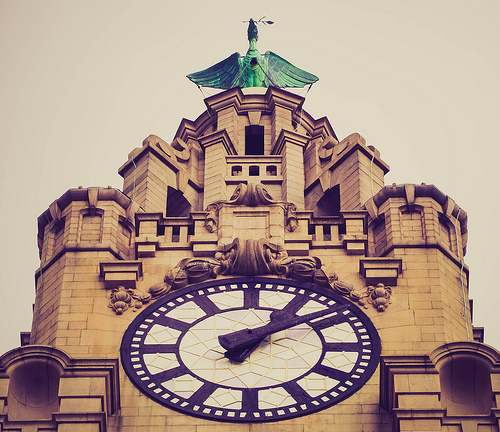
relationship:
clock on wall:
[197, 281, 362, 401] [51, 243, 466, 428]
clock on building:
[119, 278, 381, 424] [2, 8, 499, 430]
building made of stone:
[79, 175, 429, 427] [409, 257, 441, 297]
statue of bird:
[185, 16, 319, 90] [184, 12, 321, 91]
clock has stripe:
[119, 278, 381, 424] [241, 277, 262, 309]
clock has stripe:
[119, 278, 381, 424] [187, 295, 221, 319]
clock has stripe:
[119, 278, 381, 424] [149, 308, 186, 337]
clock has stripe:
[119, 278, 381, 424] [135, 337, 176, 357]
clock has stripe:
[119, 278, 381, 424] [238, 383, 261, 419]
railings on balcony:
[57, 169, 497, 251] [51, 192, 461, 268]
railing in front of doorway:
[226, 151, 283, 185] [240, 117, 269, 157]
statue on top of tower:
[183, 24, 265, 94] [178, 44, 422, 345]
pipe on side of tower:
[363, 145, 383, 203] [91, 83, 464, 353]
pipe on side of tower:
[127, 151, 138, 201] [90, 77, 458, 429]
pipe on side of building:
[32, 201, 50, 344] [0, 88, 498, 428]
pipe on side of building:
[454, 205, 474, 337] [0, 88, 498, 428]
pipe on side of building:
[370, 152, 373, 196] [0, 88, 498, 428]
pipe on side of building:
[132, 155, 137, 201] [0, 88, 498, 428]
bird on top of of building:
[184, 12, 321, 91] [0, 88, 498, 428]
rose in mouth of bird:
[238, 20, 278, 30] [198, 12, 296, 104]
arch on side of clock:
[384, 341, 496, 415] [154, 252, 350, 402]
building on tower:
[0, 88, 498, 428] [0, 47, 490, 415]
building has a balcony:
[0, 88, 498, 428] [130, 206, 372, 257]